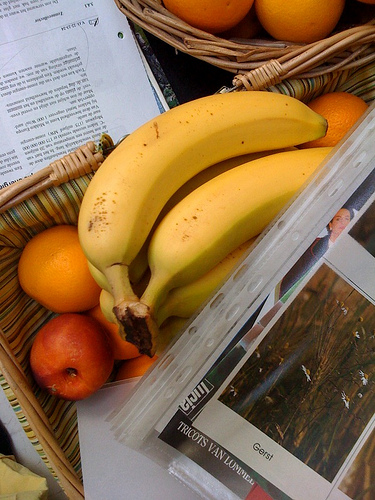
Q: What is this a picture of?
A: Fruit.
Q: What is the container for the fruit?
A: A basket.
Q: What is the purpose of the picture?
A: To show the beauty of fruit.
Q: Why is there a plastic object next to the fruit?
A: Pages from photo album.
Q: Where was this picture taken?
A: Table.